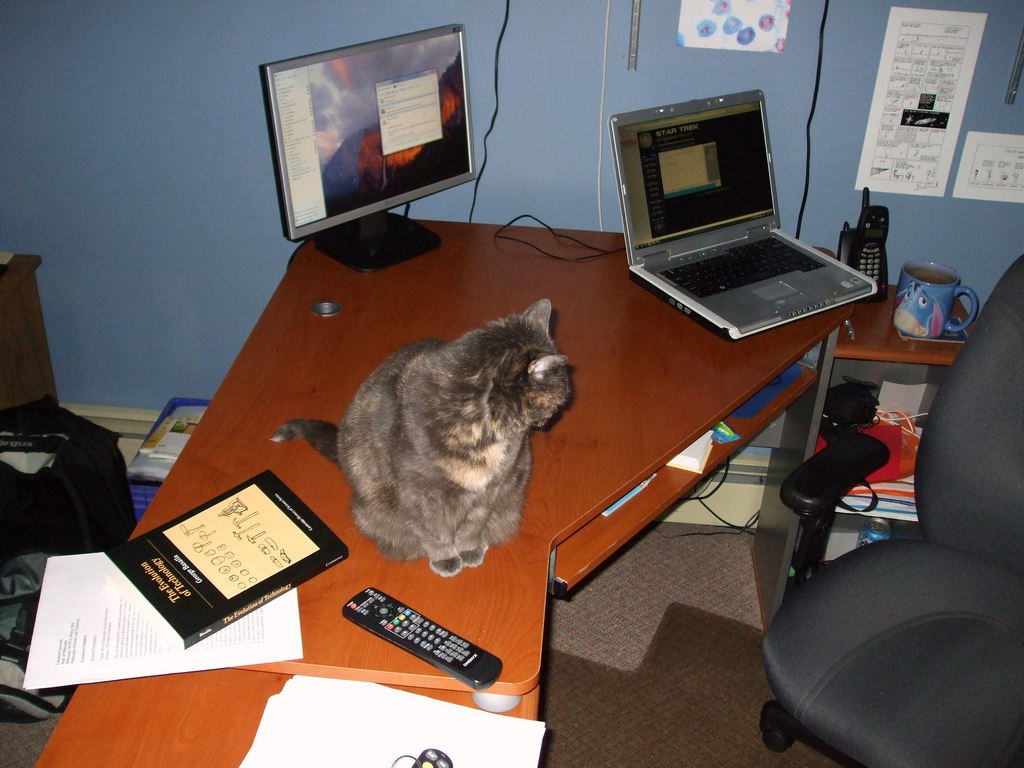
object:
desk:
[36, 219, 857, 768]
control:
[340, 587, 502, 693]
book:
[99, 470, 349, 652]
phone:
[837, 187, 891, 303]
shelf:
[830, 285, 973, 367]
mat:
[544, 603, 828, 768]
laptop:
[607, 89, 878, 342]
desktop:
[258, 22, 479, 272]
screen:
[257, 24, 478, 243]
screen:
[618, 100, 777, 250]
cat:
[266, 298, 572, 579]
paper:
[20, 552, 304, 691]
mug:
[892, 261, 980, 339]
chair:
[762, 254, 1024, 768]